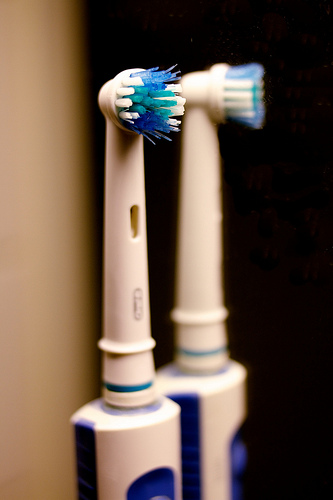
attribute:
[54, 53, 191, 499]
toothbrush — blue, white, here, electric, battery-operated, operated, battery operated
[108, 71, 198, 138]
bristles — white, blue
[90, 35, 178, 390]
brush — bristled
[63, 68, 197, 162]
head — white, round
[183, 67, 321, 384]
brush head — removable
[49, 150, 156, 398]
neck — white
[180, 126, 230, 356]
handle — white